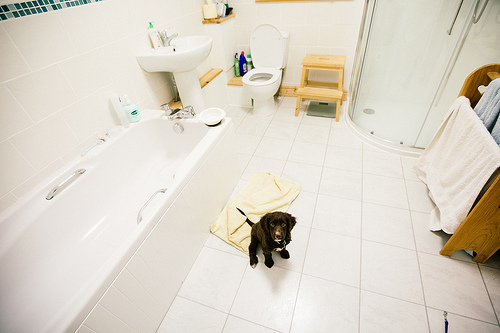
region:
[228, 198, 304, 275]
puppy sitting on bathroom floor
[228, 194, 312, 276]
puppy sitting on yellow towel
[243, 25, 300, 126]
low white toilet with raised cover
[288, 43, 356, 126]
short wooden stepstool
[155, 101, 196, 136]
silver bathtub faucet with knobs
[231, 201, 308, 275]
small brown puppy with white chest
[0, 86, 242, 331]
white bathtub with handles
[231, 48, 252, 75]
bottles of cleaning products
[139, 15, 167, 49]
bottle with green pump lid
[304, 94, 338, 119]
weight scale laying underneath stepstool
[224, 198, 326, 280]
a black dog in a white bathroom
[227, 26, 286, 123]
a white toilet with the seat up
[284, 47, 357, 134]
a tan wooden stool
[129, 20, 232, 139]
a white pedastal sink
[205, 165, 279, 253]
a biege towl on the floor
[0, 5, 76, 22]
green tiles on the top half of the wall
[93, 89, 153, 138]
bath products on the side of the tub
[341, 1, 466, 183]
a see through shower door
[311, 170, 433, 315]
a white tile floor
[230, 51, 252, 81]
cleaning products next to the toilet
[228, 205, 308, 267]
Dog on the floor.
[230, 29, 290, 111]
The toilet lid is up.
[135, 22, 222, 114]
The sink is white.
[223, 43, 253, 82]
Cleaning supplies next to the toilet.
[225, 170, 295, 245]
Towel under the dog.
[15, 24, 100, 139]
Tiles on the wall.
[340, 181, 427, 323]
Tiles on the floor.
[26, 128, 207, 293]
The bathtub is white.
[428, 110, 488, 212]
Towel on a rack.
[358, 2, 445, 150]
The shower door is clear.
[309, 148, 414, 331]
white titled floor in bathroom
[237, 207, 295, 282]
small brown and white puppy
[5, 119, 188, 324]
silver handles on white tub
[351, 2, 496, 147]
round shower in corner of bathroom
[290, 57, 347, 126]
bathroom scale under step ladder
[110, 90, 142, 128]
soap on the side of the tub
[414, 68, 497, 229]
blue and white towels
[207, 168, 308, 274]
yellow towel under puppy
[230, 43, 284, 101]
bottles of cleaner next to toilet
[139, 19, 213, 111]
white sink with silver faucet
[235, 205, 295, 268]
the small dog on the ground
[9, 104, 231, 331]
the big white bath tub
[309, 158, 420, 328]
the white tiled floor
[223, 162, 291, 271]
the yellow towel on the ground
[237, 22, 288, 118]
the white toilet bowl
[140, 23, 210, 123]
the white bathroom sink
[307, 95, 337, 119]
the scale under the stool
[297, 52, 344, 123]
the wooden stool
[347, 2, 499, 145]
the glass shower in the corner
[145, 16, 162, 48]
the hand soap on the sink